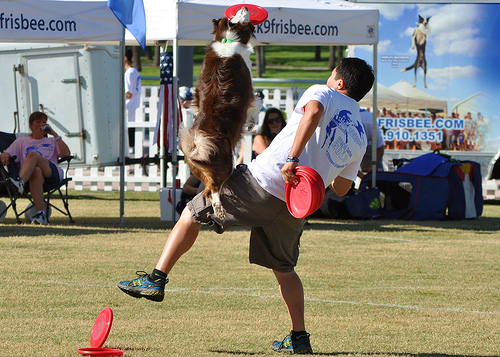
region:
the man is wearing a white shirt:
[249, 76, 371, 204]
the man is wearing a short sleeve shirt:
[244, 83, 371, 214]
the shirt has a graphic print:
[320, 105, 369, 177]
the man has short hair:
[336, 57, 376, 99]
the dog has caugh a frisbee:
[188, 5, 263, 213]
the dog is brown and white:
[183, 9, 259, 217]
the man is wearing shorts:
[196, 163, 306, 273]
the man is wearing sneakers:
[116, 269, 314, 355]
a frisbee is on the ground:
[76, 342, 121, 355]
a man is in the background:
[121, 60, 138, 119]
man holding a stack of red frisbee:
[287, 160, 325, 218]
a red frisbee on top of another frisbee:
[86, 305, 116, 344]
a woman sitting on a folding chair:
[0, 111, 80, 228]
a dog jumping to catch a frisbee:
[185, 0, 268, 221]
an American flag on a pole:
[158, 45, 183, 227]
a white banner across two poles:
[176, 3, 379, 44]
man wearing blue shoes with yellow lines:
[118, 273, 166, 302]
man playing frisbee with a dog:
[118, 3, 377, 355]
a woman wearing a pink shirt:
[6, 131, 60, 165]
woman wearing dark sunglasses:
[264, 115, 285, 127]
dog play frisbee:
[178, 2, 268, 244]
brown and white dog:
[183, 7, 260, 238]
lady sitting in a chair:
[1, 103, 83, 228]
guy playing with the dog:
[121, 0, 406, 352]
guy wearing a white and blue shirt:
[114, 46, 371, 353]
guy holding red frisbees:
[114, 39, 420, 355]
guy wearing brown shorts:
[114, 35, 373, 355]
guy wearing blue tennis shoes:
[120, 45, 394, 354]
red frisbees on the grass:
[35, 304, 174, 354]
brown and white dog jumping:
[145, 0, 303, 346]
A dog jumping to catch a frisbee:
[174, 2, 276, 233]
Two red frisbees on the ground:
[76, 305, 126, 354]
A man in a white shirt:
[114, 54, 389, 351]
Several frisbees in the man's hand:
[278, 155, 329, 225]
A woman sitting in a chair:
[0, 108, 80, 228]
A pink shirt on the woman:
[5, 129, 67, 176]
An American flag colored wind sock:
[152, 39, 187, 199]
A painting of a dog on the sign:
[403, 14, 437, 96]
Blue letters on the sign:
[370, 113, 470, 139]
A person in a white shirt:
[119, 48, 141, 150]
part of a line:
[393, 283, 415, 309]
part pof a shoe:
[127, 288, 139, 308]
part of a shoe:
[283, 322, 309, 348]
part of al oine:
[372, 275, 401, 329]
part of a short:
[275, 233, 322, 284]